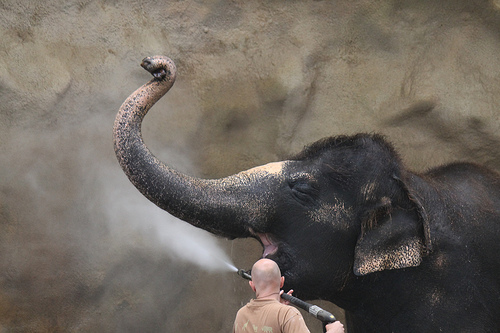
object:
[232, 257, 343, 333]
guy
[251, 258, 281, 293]
bald headed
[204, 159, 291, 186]
patch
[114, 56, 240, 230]
trunk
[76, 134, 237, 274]
spary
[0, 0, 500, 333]
wall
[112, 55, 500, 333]
elephant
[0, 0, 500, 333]
zoo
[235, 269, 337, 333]
water gun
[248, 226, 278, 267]
mouth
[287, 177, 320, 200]
eye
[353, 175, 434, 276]
ear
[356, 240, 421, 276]
discoloration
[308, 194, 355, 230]
discoloration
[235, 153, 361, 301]
face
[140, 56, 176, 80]
end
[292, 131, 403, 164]
hair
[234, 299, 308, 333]
t shirt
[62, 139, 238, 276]
water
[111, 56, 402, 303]
head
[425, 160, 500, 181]
hump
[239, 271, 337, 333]
hose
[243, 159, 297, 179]
spot